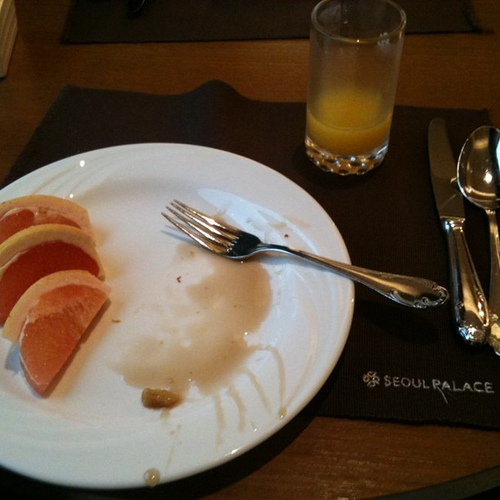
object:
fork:
[160, 198, 448, 309]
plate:
[0, 142, 356, 491]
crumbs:
[111, 232, 289, 410]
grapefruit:
[0, 193, 112, 394]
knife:
[428, 116, 490, 346]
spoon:
[456, 122, 499, 357]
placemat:
[1, 78, 499, 431]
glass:
[305, 0, 407, 176]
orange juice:
[306, 82, 394, 156]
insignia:
[362, 370, 493, 404]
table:
[0, 0, 499, 499]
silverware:
[427, 116, 500, 358]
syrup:
[108, 207, 287, 489]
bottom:
[303, 135, 390, 177]